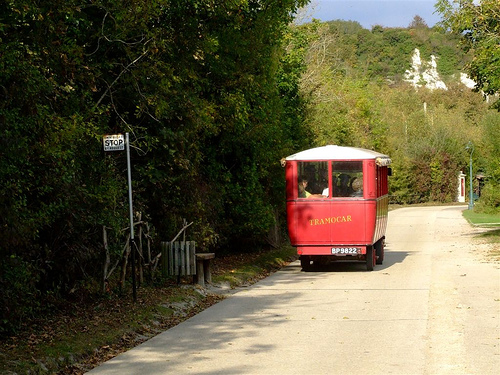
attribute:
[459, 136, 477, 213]
pole — green, in the distance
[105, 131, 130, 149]
sign — small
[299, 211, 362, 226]
writing — yellow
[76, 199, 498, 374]
road — for traveling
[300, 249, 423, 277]
shadow — from the vehicle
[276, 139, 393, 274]
vehicle — red, white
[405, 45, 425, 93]
structure — white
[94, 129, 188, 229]
sign — for traffic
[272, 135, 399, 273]
train — red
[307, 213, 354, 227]
letters — gold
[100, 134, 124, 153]
writing — black, in all caps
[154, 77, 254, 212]
trees — thick, green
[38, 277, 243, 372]
grass — green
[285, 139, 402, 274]
bus — small, red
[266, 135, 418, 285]
trolly car — red, small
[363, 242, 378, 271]
wheel — green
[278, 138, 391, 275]
train — red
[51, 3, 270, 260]
tree — green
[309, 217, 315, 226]
letter — gold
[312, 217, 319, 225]
letter — gold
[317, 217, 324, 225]
letter — gold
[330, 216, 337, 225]
letter — gold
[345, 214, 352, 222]
letter — gold